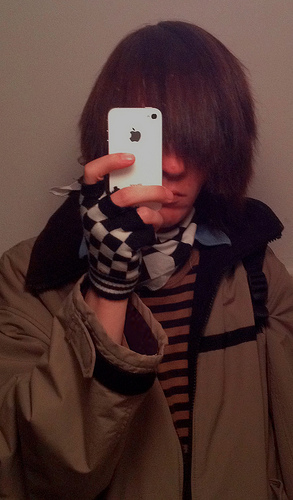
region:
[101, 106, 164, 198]
Apple phone in the hand.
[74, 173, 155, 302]
Black and checkered glove on hand.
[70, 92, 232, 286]
Black and white checkered scarf.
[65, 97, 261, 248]
Man has brown hair.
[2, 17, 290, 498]
Man is wearing brown jacket.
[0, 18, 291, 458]
Man is wearing a striped shirt.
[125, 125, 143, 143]
Apple logon on the phone.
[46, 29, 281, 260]
Blue jean collar on man's shirt.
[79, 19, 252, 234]
The man has shoulder length hair.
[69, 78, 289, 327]
Man has a black strap on his shoulder.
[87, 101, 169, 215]
white iphone being held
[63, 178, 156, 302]
Black and white fingerless gloves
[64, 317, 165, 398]
Velcro on a jacket sleeve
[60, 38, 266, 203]
Mop top style hair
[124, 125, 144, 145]
The Apple logo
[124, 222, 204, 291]
A black and white scarf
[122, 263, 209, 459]
A red and black striped shirt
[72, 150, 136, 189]
A man's right pointer finger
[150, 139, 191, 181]
A man's nose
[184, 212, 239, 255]
The denim collar of a shirt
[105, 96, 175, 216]
iphone in person's hand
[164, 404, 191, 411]
stripe on person's shirt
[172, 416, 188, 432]
stripe on person's shirt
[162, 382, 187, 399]
stripe on person's shirt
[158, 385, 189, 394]
stripe on person's shirt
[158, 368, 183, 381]
stripe on person's shirt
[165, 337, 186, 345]
stripe on person's shirt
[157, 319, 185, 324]
stripe on person's shirt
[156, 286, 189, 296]
stripe on person's shirt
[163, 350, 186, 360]
stripe on person's shirt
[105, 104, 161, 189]
an white apple iPhone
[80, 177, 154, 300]
white and black checkered fingerless gloves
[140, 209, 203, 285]
black and white checkered scarf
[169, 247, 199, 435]
a brown and black striped t-shirt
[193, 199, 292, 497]
a brown and black jacket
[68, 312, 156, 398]
a Velcro strap on the sleeve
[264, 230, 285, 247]
a zipper on the jacket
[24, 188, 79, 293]
a black collar on the jacket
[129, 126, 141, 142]
the apple logo brand name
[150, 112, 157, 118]
the camera lens view finder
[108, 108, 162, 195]
White iPhone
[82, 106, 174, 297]
white iPhone in a gloved hand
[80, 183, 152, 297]
black and white checkerboard glove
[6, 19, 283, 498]
young man taking a selfie with his smartphone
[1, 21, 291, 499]
young man with long hair covering his face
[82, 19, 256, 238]
long hair covering boys face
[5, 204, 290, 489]
beige colored jacket with black trim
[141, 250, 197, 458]
beige and black horizontal striped shirt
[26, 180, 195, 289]
black and white bandanna around neck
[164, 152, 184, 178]
young man's nose